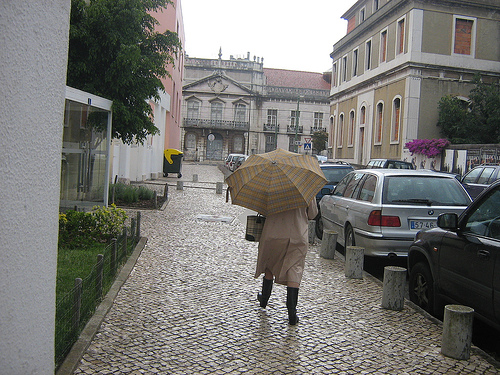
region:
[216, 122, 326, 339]
a person walking down the sidewalk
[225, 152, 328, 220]
the person is carrying an umbrella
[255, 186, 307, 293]
the person is wearing a beige coat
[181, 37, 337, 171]
a building at the end of the street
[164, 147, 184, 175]
a yellow and black bin on the sidewalk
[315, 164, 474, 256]
a silver car on the street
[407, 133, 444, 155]
purple flowers on the wall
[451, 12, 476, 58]
a boarded-up window on a building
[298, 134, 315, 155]
a street sign at the end of the road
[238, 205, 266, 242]
the person is carrying a bag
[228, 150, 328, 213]
grey and yellow plaid umbrella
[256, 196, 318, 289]
tan polyester trench coat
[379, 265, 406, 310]
metal ash can on sidewalk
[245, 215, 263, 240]
yellow and grey tote bag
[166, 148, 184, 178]
yellow and green dumpster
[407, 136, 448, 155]
tree with pink flowers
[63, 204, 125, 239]
bush with yellow flowers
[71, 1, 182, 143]
tree with green leaves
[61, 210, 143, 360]
metal and wood fence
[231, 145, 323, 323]
person holding plaid umbrella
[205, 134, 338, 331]
A person walking in the rain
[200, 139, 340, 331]
A woman walking in the rain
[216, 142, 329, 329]
A woman holding an umbrella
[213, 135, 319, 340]
A woman holding an umbrella and wearing boots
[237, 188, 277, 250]
A woman holding a purse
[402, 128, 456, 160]
Purple flowers on a wall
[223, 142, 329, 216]
A striped umbrella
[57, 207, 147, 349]
A small fence near the grass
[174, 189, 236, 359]
A cobblestone sidewalk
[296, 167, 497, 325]
Cars parked near the street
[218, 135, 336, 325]
woman walking down the street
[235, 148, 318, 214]
umbrella on woman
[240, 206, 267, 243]
black and white purse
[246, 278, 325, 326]
black boots on feet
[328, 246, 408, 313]
side walk posts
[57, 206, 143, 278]
garden of plants by side walk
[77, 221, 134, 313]
small black metal fence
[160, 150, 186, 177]
green and yellow trash can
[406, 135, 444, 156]
purple flowers growing by wall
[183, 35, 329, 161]
large old building in front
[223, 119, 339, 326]
a woman carrying a umbrella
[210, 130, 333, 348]
a woman walking under a umbrella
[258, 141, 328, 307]
a woman wearing a rain coat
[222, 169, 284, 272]
a woman carrying a purse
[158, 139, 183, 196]
a small garbage dumpster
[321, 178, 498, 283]
two cars parked next to a curb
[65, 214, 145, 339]
a small fence next to a sidewalk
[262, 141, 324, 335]
a woman wearing black boots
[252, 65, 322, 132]
a building with a red roof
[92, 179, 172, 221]
small flower bed